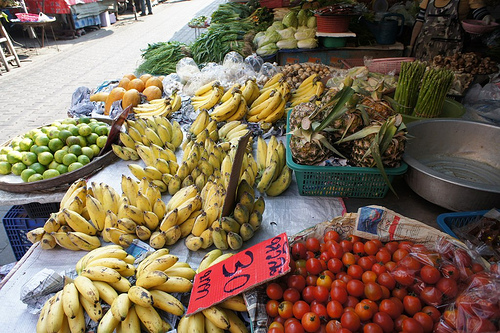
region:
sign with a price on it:
[197, 235, 288, 310]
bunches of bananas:
[57, 180, 182, 327]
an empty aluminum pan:
[405, 105, 496, 210]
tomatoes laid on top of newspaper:
[291, 200, 361, 326]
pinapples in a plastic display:
[285, 96, 402, 196]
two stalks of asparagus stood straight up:
[386, 45, 456, 127]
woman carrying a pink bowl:
[385, 1, 495, 67]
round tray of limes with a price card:
[0, 110, 125, 190]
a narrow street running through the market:
[5, 1, 170, 121]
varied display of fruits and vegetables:
[17, 5, 470, 325]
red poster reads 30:
[186, 226, 303, 324]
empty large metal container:
[390, 107, 499, 217]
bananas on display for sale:
[38, 80, 281, 322]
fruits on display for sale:
[7, 112, 121, 190]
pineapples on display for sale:
[286, 71, 406, 188]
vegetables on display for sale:
[386, 53, 460, 130]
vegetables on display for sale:
[243, 7, 335, 64]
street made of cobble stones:
[2, 6, 196, 142]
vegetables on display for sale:
[178, 5, 259, 77]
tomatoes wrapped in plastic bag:
[413, 251, 498, 332]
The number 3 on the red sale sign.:
[215, 251, 257, 270]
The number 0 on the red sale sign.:
[218, 268, 255, 289]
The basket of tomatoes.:
[261, 218, 473, 320]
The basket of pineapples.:
[280, 93, 402, 175]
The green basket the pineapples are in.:
[279, 102, 406, 199]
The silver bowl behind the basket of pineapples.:
[396, 109, 499, 206]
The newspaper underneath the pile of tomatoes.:
[247, 212, 494, 332]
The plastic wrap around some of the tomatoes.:
[415, 229, 499, 332]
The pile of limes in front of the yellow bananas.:
[4, 125, 109, 171]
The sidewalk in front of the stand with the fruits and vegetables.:
[3, 5, 160, 122]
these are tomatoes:
[253, 218, 495, 330]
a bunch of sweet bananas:
[44, 242, 131, 331]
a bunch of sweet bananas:
[101, 251, 193, 330]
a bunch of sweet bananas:
[178, 247, 244, 331]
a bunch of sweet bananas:
[30, 178, 105, 253]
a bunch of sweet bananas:
[63, 182, 125, 249]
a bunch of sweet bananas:
[143, 180, 212, 246]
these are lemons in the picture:
[2, 111, 119, 181]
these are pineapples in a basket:
[277, 95, 407, 197]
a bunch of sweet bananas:
[247, 72, 302, 122]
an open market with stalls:
[6, 0, 490, 328]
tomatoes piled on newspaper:
[253, 220, 488, 332]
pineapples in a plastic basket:
[286, 101, 408, 201]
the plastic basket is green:
[283, 106, 405, 200]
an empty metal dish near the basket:
[405, 116, 499, 207]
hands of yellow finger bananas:
[38, 117, 281, 326]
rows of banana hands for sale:
[129, 77, 333, 126]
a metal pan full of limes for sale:
[0, 117, 114, 187]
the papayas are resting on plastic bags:
[91, 70, 163, 118]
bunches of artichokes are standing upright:
[389, 58, 459, 122]